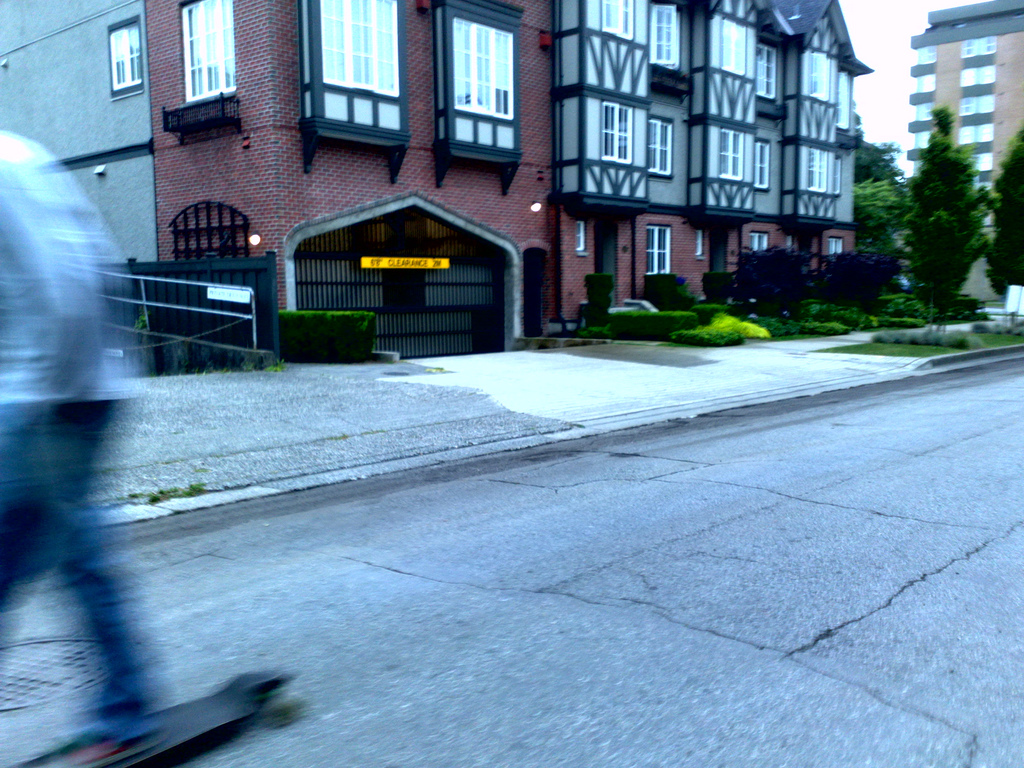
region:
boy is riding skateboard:
[0, 125, 163, 762]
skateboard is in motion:
[11, 668, 286, 764]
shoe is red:
[39, 725, 158, 761]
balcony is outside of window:
[156, 92, 236, 140]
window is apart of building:
[437, 2, 518, 187]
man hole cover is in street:
[0, 627, 138, 710]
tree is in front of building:
[902, 100, 1001, 332]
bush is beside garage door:
[276, 311, 375, 363]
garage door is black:
[288, 198, 526, 358]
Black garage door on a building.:
[296, 227, 503, 373]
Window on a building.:
[599, 101, 634, 168]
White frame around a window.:
[631, 222, 680, 279]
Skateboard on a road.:
[40, 666, 272, 765]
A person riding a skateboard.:
[2, 126, 170, 760]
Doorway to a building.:
[590, 208, 625, 322]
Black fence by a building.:
[89, 249, 286, 352]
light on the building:
[528, 195, 548, 222]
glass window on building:
[597, 97, 616, 159]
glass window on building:
[611, 107, 630, 165]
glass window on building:
[642, 122, 669, 168]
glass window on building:
[750, 137, 771, 188]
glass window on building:
[643, 226, 670, 272]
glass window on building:
[178, 7, 232, 99]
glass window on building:
[313, 0, 405, 94]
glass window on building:
[104, 20, 143, 96]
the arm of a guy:
[0, 145, 117, 405]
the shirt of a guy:
[2, 142, 151, 417]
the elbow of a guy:
[38, 265, 119, 338]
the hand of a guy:
[5, 338, 95, 411]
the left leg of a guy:
[17, 414, 116, 589]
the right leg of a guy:
[5, 464, 186, 739]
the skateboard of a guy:
[35, 657, 292, 765]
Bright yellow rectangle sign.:
[357, 254, 452, 273]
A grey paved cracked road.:
[3, 369, 1022, 766]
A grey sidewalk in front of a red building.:
[771, 318, 1013, 354]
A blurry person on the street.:
[2, 131, 168, 767]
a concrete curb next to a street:
[564, 387, 799, 438]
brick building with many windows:
[2, 0, 875, 377]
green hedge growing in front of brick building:
[583, 275, 612, 332]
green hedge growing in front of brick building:
[647, 272, 680, 308]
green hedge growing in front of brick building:
[703, 274, 735, 306]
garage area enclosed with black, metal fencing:
[296, 208, 509, 376]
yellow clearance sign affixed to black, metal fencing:
[358, 256, 454, 272]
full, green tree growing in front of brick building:
[908, 101, 995, 337]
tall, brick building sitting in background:
[909, 0, 1021, 303]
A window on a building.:
[449, 23, 472, 100]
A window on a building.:
[465, 29, 484, 106]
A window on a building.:
[492, 26, 506, 116]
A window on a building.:
[603, 98, 636, 159]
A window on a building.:
[644, 117, 676, 172]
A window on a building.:
[716, 128, 749, 177]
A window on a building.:
[647, 216, 677, 271]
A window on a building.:
[694, 228, 701, 255]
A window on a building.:
[568, 220, 588, 249]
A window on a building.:
[97, 27, 135, 91]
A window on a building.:
[599, 93, 639, 170]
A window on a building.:
[656, 115, 683, 167]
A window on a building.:
[713, 121, 749, 175]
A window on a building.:
[748, 136, 777, 188]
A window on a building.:
[799, 149, 835, 188]